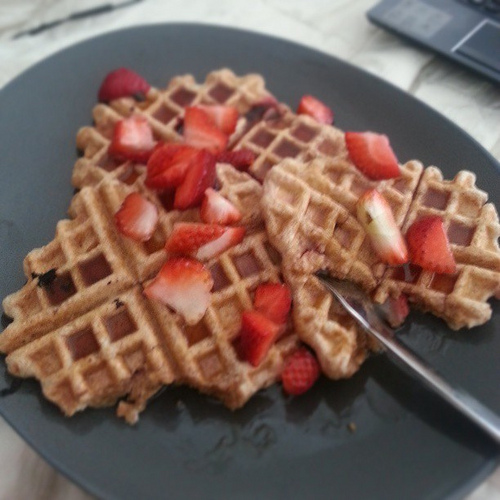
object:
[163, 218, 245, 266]
strawberries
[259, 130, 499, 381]
waffles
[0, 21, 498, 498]
plate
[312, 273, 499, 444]
fork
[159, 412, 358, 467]
syrup